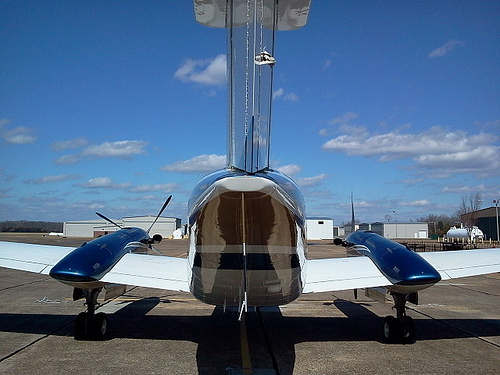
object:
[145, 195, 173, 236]
propeller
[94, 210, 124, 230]
propeller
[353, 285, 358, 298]
propeller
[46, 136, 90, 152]
cloud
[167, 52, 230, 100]
cloud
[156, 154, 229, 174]
cloud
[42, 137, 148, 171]
cloud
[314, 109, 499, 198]
cloud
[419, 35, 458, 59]
cloud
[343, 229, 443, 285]
engine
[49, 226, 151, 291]
engine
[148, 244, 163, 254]
propeller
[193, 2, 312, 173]
tail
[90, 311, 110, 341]
wheel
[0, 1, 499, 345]
jet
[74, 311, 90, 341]
wheel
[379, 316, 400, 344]
wheel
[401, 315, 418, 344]
wheel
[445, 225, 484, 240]
tank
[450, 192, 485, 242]
tree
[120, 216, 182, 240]
building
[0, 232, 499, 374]
tarmac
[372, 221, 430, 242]
building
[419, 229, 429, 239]
door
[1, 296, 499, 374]
shadow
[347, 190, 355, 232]
propeller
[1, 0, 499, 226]
sky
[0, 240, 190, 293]
wing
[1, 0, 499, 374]
background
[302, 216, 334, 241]
building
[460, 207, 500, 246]
building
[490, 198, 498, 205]
street light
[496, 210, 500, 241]
pole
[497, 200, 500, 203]
street light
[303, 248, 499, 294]
wing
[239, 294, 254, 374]
line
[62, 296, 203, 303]
line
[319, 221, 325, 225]
rectangle